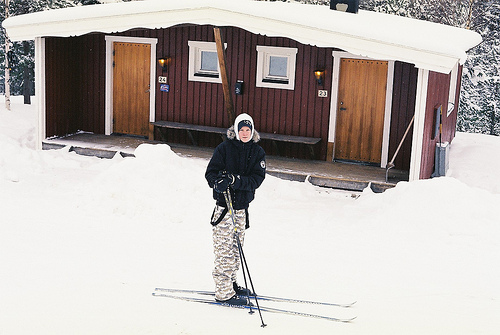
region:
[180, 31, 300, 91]
Two windows on a house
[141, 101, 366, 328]
A person is about to go skiing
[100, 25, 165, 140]
A brown door on a house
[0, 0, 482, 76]
Snow is on the house's roof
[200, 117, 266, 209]
Black jacket with a fur hood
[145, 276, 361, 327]
Two boots on two skis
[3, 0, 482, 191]
two door cabin with snow on roof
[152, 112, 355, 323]
person standing on skis in the snow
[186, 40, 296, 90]
two identical square windows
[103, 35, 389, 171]
glowing lights next to two doors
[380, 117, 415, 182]
shovel with handle leaning against wall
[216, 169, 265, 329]
two ski poles in gloved hands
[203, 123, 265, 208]
winter jacket with fur lined hood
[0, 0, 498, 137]
snow covered trees behind cabin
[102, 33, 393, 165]
flat bench between two doors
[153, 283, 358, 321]
boots attached to two skis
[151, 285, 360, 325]
Two skis in the snow.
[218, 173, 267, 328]
Two ski poles.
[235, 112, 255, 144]
White hood on a persons head.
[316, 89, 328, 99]
White sign that has 23 on it.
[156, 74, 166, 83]
White sign that says 24.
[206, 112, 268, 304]
A person in a white hood and black coat.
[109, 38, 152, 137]
Brown door for number 24.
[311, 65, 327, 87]
Black light fixture for number 23 cabin.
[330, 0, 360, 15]
A black chimney above cabin 23.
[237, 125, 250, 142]
Face of a person.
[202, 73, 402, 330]
a perons on skis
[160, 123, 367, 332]
a person standing on ski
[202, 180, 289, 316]
a person holding a pole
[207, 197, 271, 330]
a person holding pole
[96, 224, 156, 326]
ground covered in snow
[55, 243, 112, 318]
snow covering the ground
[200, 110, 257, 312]
A person dressed in winter attire.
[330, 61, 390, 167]
A door on a building.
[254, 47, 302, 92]
A small white window on a building.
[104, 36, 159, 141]
A brown and white door.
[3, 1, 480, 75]
A snow covered white roof.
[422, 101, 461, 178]
Luggage on the side of a house.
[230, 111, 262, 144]
A man in a hat.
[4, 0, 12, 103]
A tree in a forest.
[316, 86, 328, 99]
a number near a door.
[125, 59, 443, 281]
this is a person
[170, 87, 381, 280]
the person is alone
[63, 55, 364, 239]
this is winter time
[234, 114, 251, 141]
head of a person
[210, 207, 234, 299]
leg of a person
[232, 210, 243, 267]
leg of a person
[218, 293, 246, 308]
foot of a person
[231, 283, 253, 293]
foot of a person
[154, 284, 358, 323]
a pair of skis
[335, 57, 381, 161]
the door is wood